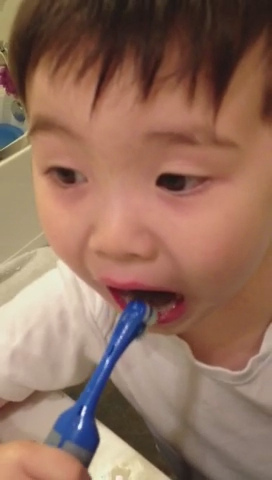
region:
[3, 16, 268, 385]
A baby brushing his teeth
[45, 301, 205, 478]
A blue baby brush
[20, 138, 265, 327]
A brown boy's face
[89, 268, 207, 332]
A brown boy's open mouth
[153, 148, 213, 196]
A brown boy's eye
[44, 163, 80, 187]
A brown boy's eye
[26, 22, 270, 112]
A brown boy's hair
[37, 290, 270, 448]
A brown boy's white shirt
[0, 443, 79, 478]
A brown boy's hand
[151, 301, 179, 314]
A brown boy's teeth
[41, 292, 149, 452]
the toothbrush is blue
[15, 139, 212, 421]
boy is brushing his teeth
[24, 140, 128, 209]
the eye of a boy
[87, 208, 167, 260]
the nose of a boy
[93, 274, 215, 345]
the lips of a boy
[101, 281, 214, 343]
the teeth of a boy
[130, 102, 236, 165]
the eye brow of a boy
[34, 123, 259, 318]
the head of a boy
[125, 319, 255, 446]
the collar on a shirt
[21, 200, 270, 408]
a boy wearing a white shirt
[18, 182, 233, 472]
a boy holding a toothbrush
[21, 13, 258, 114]
the hair of a boy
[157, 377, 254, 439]
Crisp white baby tee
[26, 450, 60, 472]
Small baby index finger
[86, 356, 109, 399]
Narrow part of toothbrush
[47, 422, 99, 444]
Blue wide toothbrush handle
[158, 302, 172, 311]
Clean white baby teeth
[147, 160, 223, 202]
A black and white eye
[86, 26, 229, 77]
Short black colored hair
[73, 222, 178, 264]
A small wide nose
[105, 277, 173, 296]
Tomato red small lips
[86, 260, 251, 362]
Boy brushing his teeth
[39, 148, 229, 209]
eye of a child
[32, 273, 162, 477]
a blue tooth brush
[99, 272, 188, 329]
mouth of a child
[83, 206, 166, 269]
nose of a child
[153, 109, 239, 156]
eye brows of a child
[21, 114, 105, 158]
eye brow of a child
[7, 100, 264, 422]
child brushing teeth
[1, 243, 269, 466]
a white shirt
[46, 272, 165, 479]
child holding a toothbrush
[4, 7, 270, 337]
head of a child